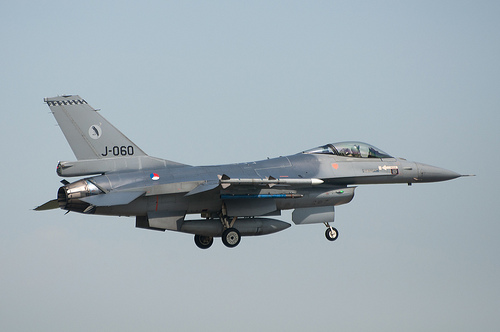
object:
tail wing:
[43, 94, 146, 159]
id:
[102, 145, 134, 156]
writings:
[102, 143, 135, 157]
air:
[44, 15, 472, 41]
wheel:
[222, 228, 241, 248]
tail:
[32, 92, 141, 217]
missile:
[217, 174, 325, 185]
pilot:
[308, 141, 397, 174]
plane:
[32, 92, 478, 249]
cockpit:
[302, 141, 394, 158]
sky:
[2, 2, 498, 329]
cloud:
[1, 235, 498, 326]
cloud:
[206, 50, 377, 100]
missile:
[167, 217, 292, 237]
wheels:
[193, 234, 214, 249]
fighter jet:
[31, 94, 479, 248]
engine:
[57, 179, 102, 216]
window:
[304, 141, 394, 159]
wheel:
[324, 227, 340, 242]